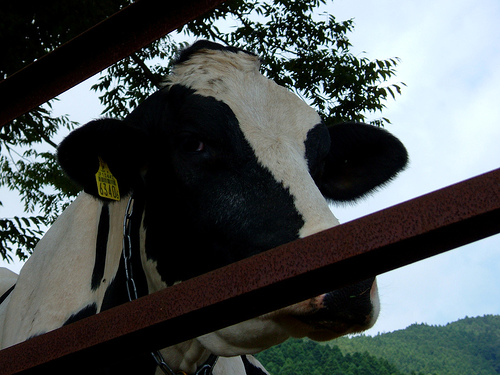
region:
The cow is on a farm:
[11, 26, 481, 333]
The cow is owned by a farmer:
[11, 30, 476, 341]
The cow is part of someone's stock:
[11, 35, 479, 373]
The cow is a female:
[5, 17, 488, 345]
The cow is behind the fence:
[45, 35, 475, 351]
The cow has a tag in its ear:
[11, 20, 461, 346]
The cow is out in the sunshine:
[20, 21, 477, 349]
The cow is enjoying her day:
[8, 28, 478, 355]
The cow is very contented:
[7, 12, 467, 344]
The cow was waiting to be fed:
[10, 27, 461, 351]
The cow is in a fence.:
[3, 60, 375, 371]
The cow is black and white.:
[4, 39, 403, 359]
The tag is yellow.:
[87, 165, 132, 219]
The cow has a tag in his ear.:
[35, 38, 428, 363]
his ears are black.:
[50, 112, 422, 214]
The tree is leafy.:
[4, 5, 378, 135]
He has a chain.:
[103, 205, 197, 374]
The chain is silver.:
[111, 198, 176, 373]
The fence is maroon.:
[36, 153, 493, 373]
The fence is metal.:
[65, 163, 492, 368]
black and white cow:
[52, 95, 411, 358]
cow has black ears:
[54, 98, 411, 240]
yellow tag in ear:
[93, 161, 121, 196]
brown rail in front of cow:
[55, 141, 483, 373]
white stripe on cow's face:
[201, 62, 350, 266]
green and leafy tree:
[127, 0, 402, 146]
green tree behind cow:
[117, 27, 376, 137]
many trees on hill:
[332, 309, 493, 367]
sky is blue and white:
[377, 9, 461, 140]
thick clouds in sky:
[377, 11, 486, 123]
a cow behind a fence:
[13, 33, 418, 371]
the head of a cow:
[31, 33, 409, 346]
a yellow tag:
[84, 157, 130, 204]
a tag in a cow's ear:
[87, 151, 131, 213]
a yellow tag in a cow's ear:
[87, 149, 128, 204]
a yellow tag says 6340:
[94, 178, 124, 203]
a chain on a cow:
[120, 206, 209, 374]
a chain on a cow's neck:
[115, 188, 220, 374]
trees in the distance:
[253, 318, 495, 374]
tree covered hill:
[255, 312, 498, 374]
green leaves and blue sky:
[283, 2, 497, 104]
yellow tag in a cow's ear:
[56, 106, 154, 216]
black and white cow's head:
[55, 31, 408, 341]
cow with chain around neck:
[48, 34, 386, 372]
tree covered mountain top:
[382, 283, 499, 372]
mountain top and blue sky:
[385, 274, 497, 373]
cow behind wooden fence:
[9, 6, 411, 373]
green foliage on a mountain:
[383, 308, 499, 372]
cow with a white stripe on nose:
[53, 27, 398, 329]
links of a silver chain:
[118, 193, 150, 308]